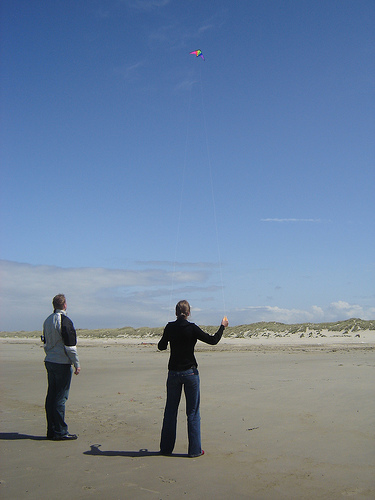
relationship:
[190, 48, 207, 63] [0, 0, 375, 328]
kite in blue sky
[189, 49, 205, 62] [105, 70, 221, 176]
kite in sky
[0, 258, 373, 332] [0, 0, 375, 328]
clouds in blue sky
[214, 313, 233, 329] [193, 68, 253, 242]
hand holding string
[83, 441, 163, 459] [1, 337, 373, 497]
shadow on beach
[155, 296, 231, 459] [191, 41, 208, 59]
lady flying kite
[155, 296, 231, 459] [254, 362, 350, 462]
lady on sand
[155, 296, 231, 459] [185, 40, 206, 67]
lady flying kite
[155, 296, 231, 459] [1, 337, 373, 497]
lady on beach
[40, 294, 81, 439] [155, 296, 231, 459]
man watching lady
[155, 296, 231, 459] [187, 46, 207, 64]
lady flying kite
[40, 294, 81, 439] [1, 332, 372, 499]
man on sand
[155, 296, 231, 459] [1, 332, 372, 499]
lady on sand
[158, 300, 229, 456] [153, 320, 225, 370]
lady wearing black shirt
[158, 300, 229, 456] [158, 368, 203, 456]
lady wearing blue jeans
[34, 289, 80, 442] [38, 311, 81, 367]
man wearing coat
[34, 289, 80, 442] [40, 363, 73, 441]
man wearing jeans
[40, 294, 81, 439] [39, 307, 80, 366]
man wearing coat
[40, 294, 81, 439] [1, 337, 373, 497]
man on beach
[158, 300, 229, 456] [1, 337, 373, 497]
lady on beach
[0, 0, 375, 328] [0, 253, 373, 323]
blue sky has clouds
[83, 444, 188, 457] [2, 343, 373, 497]
shadow on ground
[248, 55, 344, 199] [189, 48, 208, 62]
blue sky with kite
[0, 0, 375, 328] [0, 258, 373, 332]
blue sky with clouds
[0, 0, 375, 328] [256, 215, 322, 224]
blue sky with clouds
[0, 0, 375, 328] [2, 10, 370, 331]
blue sky has clouds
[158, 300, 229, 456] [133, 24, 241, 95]
lady flying a kite.